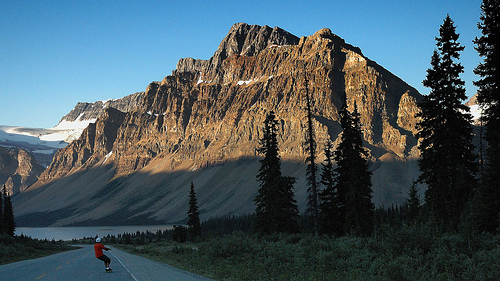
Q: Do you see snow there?
A: Yes, there is snow.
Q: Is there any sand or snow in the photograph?
A: Yes, there is snow.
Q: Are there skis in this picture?
A: No, there are no skis.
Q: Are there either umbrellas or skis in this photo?
A: No, there are no skis or umbrellas.